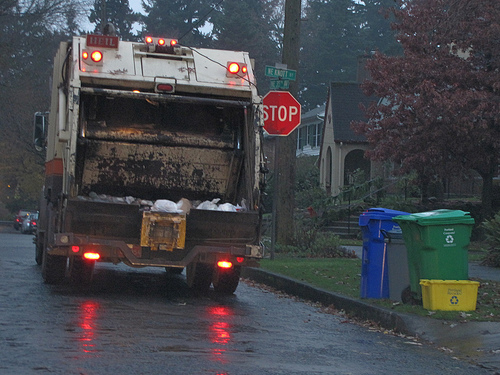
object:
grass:
[251, 249, 497, 323]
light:
[84, 251, 101, 260]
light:
[237, 256, 245, 262]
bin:
[419, 278, 481, 311]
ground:
[12, 284, 418, 373]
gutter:
[286, 286, 386, 357]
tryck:
[30, 30, 260, 303]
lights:
[82, 50, 248, 74]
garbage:
[78, 191, 248, 215]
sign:
[262, 90, 302, 136]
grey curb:
[240, 266, 438, 343]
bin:
[391, 208, 475, 304]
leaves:
[239, 255, 424, 346]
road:
[0, 221, 500, 375]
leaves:
[355, 0, 500, 172]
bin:
[358, 207, 413, 299]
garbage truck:
[31, 22, 271, 293]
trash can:
[380, 225, 411, 303]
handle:
[380, 229, 392, 239]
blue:
[367, 222, 375, 274]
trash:
[358, 207, 412, 299]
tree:
[348, 0, 500, 242]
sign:
[264, 65, 297, 90]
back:
[41, 34, 262, 293]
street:
[0, 228, 500, 375]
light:
[217, 260, 233, 269]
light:
[72, 245, 80, 252]